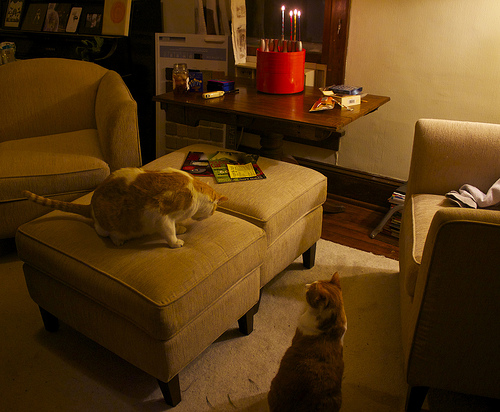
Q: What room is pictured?
A: It is a living room.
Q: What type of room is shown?
A: It is a living room.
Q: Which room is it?
A: It is a living room.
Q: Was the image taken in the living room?
A: Yes, it was taken in the living room.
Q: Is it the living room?
A: Yes, it is the living room.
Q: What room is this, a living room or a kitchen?
A: It is a living room.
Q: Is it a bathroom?
A: No, it is a living room.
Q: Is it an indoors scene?
A: Yes, it is indoors.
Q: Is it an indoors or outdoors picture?
A: It is indoors.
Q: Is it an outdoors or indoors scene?
A: It is indoors.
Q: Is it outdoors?
A: No, it is indoors.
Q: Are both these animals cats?
A: Yes, all the animals are cats.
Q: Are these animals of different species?
A: No, all the animals are cats.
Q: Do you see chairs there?
A: Yes, there is a chair.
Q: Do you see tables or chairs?
A: Yes, there is a chair.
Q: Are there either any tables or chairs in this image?
A: Yes, there is a chair.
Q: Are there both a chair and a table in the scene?
A: Yes, there are both a chair and a table.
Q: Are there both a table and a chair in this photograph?
A: Yes, there are both a chair and a table.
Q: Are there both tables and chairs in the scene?
A: Yes, there are both a chair and a table.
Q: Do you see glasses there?
A: No, there are no glasses.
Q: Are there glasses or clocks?
A: No, there are no glasses or clocks.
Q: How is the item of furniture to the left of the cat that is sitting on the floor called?
A: The piece of furniture is a chair.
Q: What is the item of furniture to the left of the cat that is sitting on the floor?
A: The piece of furniture is a chair.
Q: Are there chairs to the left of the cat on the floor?
A: Yes, there is a chair to the left of the cat.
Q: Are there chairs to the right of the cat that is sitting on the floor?
A: No, the chair is to the left of the cat.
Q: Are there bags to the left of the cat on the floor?
A: No, there is a chair to the left of the cat.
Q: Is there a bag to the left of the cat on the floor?
A: No, there is a chair to the left of the cat.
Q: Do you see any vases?
A: No, there are no vases.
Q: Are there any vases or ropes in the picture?
A: No, there are no vases or ropes.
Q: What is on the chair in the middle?
A: The magazine is on the chair.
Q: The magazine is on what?
A: The magazine is on the chair.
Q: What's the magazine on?
A: The magazine is on the chair.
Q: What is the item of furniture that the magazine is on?
A: The piece of furniture is a chair.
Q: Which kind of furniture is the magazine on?
A: The magazine is on the chair.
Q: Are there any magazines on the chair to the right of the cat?
A: Yes, there is a magazine on the chair.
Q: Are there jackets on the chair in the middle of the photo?
A: No, there is a magazine on the chair.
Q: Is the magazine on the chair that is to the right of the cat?
A: Yes, the magazine is on the chair.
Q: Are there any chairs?
A: Yes, there is a chair.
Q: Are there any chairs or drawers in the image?
A: Yes, there is a chair.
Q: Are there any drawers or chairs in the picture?
A: Yes, there is a chair.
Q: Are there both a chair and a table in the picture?
A: Yes, there are both a chair and a table.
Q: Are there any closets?
A: No, there are no closets.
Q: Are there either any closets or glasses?
A: No, there are no closets or glasses.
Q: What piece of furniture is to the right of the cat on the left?
A: The piece of furniture is a chair.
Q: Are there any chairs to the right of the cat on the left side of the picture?
A: Yes, there is a chair to the right of the cat.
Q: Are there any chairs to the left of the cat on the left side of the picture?
A: No, the chair is to the right of the cat.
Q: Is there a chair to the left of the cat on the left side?
A: No, the chair is to the right of the cat.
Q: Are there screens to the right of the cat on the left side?
A: No, there is a chair to the right of the cat.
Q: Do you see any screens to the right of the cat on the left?
A: No, there is a chair to the right of the cat.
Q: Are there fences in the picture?
A: No, there are no fences.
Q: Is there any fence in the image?
A: No, there are no fences.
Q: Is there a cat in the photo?
A: Yes, there is a cat.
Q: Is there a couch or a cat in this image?
A: Yes, there is a cat.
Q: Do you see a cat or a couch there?
A: Yes, there is a cat.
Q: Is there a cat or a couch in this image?
A: Yes, there is a cat.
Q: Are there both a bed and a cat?
A: No, there is a cat but no beds.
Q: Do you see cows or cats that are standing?
A: Yes, the cat is standing.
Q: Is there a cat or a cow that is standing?
A: Yes, the cat is standing.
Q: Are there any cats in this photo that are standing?
A: Yes, there is a cat that is standing.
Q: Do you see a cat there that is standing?
A: Yes, there is a cat that is standing.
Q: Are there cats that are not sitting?
A: Yes, there is a cat that is standing.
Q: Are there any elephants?
A: No, there are no elephants.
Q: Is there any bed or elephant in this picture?
A: No, there are no elephants or beds.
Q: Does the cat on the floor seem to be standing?
A: Yes, the cat is standing.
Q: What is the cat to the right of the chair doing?
A: The cat is standing.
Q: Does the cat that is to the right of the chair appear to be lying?
A: No, the cat is standing.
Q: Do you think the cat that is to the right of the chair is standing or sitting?
A: The cat is standing.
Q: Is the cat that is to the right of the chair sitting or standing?
A: The cat is standing.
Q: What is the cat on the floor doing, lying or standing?
A: The cat is standing.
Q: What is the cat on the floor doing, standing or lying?
A: The cat is standing.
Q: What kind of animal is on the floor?
A: The animal is a cat.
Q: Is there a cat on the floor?
A: Yes, there is a cat on the floor.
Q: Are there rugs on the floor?
A: No, there is a cat on the floor.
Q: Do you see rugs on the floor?
A: No, there is a cat on the floor.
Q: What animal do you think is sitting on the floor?
A: The cat is sitting on the floor.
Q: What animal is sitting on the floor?
A: The cat is sitting on the floor.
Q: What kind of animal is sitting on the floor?
A: The animal is a cat.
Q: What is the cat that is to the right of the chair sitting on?
A: The cat is sitting on the floor.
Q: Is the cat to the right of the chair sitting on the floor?
A: Yes, the cat is sitting on the floor.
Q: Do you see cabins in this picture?
A: No, there are no cabins.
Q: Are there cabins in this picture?
A: No, there are no cabins.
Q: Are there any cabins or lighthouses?
A: No, there are no cabins or lighthouses.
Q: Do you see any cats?
A: Yes, there is a cat.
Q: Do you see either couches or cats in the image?
A: Yes, there is a cat.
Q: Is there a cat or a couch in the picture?
A: Yes, there is a cat.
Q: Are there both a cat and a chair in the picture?
A: Yes, there are both a cat and a chair.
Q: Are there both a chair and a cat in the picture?
A: Yes, there are both a cat and a chair.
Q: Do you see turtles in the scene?
A: No, there are no turtles.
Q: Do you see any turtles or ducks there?
A: No, there are no turtles or ducks.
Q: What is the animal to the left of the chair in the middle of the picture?
A: The animal is a cat.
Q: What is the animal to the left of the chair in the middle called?
A: The animal is a cat.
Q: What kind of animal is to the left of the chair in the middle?
A: The animal is a cat.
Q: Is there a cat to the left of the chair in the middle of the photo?
A: Yes, there is a cat to the left of the chair.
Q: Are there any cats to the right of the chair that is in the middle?
A: No, the cat is to the left of the chair.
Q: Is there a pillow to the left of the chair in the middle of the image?
A: No, there is a cat to the left of the chair.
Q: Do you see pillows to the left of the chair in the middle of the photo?
A: No, there is a cat to the left of the chair.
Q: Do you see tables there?
A: Yes, there is a table.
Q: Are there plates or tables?
A: Yes, there is a table.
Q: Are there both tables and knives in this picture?
A: No, there is a table but no knives.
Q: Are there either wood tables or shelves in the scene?
A: Yes, there is a wood table.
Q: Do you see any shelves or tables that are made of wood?
A: Yes, the table is made of wood.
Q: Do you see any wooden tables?
A: Yes, there is a wood table.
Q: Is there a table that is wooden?
A: Yes, there is a table that is wooden.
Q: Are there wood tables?
A: Yes, there is a table that is made of wood.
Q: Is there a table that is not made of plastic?
A: Yes, there is a table that is made of wood.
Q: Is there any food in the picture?
A: No, there is no food.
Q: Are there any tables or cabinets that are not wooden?
A: No, there is a table but it is wooden.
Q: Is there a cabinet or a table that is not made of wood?
A: No, there is a table but it is made of wood.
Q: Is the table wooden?
A: Yes, the table is wooden.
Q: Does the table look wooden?
A: Yes, the table is wooden.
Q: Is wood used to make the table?
A: Yes, the table is made of wood.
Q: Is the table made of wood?
A: Yes, the table is made of wood.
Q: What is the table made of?
A: The table is made of wood.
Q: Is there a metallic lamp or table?
A: No, there is a table but it is wooden.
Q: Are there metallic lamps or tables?
A: No, there is a table but it is wooden.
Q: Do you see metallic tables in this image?
A: No, there is a table but it is wooden.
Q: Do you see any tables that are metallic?
A: No, there is a table but it is wooden.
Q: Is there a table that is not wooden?
A: No, there is a table but it is wooden.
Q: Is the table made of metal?
A: No, the table is made of wood.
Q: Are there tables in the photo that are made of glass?
A: No, there is a table but it is made of wood.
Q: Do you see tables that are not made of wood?
A: No, there is a table but it is made of wood.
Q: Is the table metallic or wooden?
A: The table is wooden.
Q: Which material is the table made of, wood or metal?
A: The table is made of wood.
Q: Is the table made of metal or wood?
A: The table is made of wood.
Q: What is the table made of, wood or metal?
A: The table is made of wood.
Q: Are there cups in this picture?
A: Yes, there is a cup.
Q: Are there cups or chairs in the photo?
A: Yes, there is a cup.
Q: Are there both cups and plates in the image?
A: No, there is a cup but no plates.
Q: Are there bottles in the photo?
A: No, there are no bottles.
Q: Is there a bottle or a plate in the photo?
A: No, there are no bottles or plates.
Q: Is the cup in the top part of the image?
A: Yes, the cup is in the top of the image.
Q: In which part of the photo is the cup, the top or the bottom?
A: The cup is in the top of the image.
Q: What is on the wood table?
A: The cup is on the table.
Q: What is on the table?
A: The cup is on the table.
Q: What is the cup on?
A: The cup is on the table.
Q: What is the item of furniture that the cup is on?
A: The piece of furniture is a table.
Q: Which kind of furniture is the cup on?
A: The cup is on the table.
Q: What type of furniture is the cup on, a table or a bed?
A: The cup is on a table.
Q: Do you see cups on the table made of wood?
A: Yes, there is a cup on the table.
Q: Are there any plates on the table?
A: No, there is a cup on the table.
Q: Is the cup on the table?
A: Yes, the cup is on the table.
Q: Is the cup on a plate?
A: No, the cup is on the table.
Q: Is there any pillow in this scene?
A: No, there are no pillows.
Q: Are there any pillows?
A: No, there are no pillows.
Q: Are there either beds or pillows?
A: No, there are no pillows or beds.